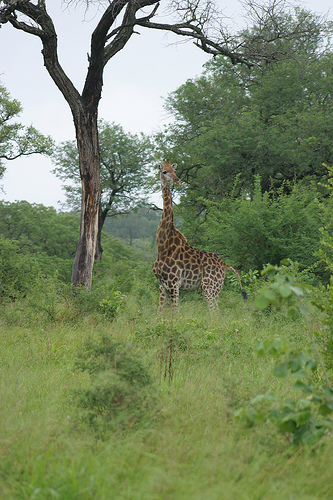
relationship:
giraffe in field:
[152, 158, 248, 323] [1, 236, 331, 498]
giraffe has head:
[152, 158, 248, 323] [158, 159, 181, 186]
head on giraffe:
[158, 159, 181, 186] [152, 158, 248, 323]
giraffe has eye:
[152, 158, 248, 323] [161, 170, 169, 175]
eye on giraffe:
[161, 170, 169, 175] [152, 158, 248, 323]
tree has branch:
[0, 84, 58, 204] [0, 110, 19, 124]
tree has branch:
[0, 84, 58, 204] [0, 145, 48, 161]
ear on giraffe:
[171, 163, 178, 170] [152, 158, 248, 323]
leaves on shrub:
[252, 281, 310, 310] [252, 274, 303, 312]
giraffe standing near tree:
[152, 158, 248, 323] [32, 36, 141, 265]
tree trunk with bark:
[68, 155, 141, 254] [75, 183, 107, 305]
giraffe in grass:
[152, 158, 248, 323] [0, 236, 332, 499]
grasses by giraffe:
[20, 345, 182, 452] [126, 138, 249, 308]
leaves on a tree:
[176, 10, 328, 191] [151, 0, 332, 248]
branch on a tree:
[135, 17, 256, 69] [1, 0, 267, 296]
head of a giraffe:
[138, 147, 190, 203] [109, 154, 246, 303]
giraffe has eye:
[152, 158, 248, 323] [162, 168, 169, 174]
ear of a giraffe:
[171, 160, 179, 170] [152, 158, 248, 323]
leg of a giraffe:
[155, 277, 167, 317] [127, 147, 246, 327]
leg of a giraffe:
[203, 285, 221, 317] [148, 152, 250, 313]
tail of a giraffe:
[223, 263, 242, 303] [152, 158, 248, 323]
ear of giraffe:
[154, 161, 167, 176] [118, 138, 223, 302]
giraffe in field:
[152, 158, 248, 323] [10, 325, 318, 482]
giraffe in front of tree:
[152, 158, 248, 323] [24, 11, 161, 123]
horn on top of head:
[160, 157, 164, 164] [153, 160, 184, 192]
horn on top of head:
[167, 157, 169, 161] [153, 160, 184, 192]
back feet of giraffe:
[202, 275, 224, 323] [152, 158, 248, 323]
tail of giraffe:
[224, 264, 248, 301] [152, 158, 248, 323]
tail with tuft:
[224, 264, 248, 301] [235, 283, 249, 303]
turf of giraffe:
[238, 287, 248, 299] [152, 158, 248, 323]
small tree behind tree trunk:
[48, 117, 163, 283] [70, 108, 102, 294]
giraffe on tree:
[131, 151, 262, 315] [33, 7, 145, 260]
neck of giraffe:
[156, 184, 177, 227] [137, 142, 254, 383]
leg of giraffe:
[160, 280, 186, 345] [131, 151, 262, 315]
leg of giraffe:
[155, 277, 167, 317] [131, 151, 262, 315]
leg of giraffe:
[203, 285, 221, 317] [131, 151, 262, 315]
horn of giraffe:
[162, 158, 165, 162] [130, 151, 260, 333]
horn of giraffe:
[167, 157, 169, 161] [130, 151, 260, 333]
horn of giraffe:
[162, 158, 165, 162] [140, 144, 216, 197]